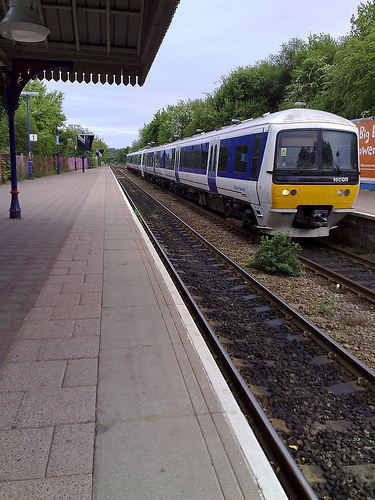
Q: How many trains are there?
A: One.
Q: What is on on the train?
A: Lights.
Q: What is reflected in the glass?
A: Trees.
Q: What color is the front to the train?
A: Yellow.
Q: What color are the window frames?
A: Blue.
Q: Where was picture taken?
A: At a train station.